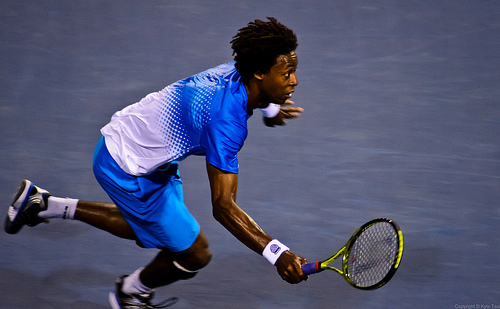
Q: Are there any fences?
A: No, there are no fences.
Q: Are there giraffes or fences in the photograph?
A: No, there are no fences or giraffes.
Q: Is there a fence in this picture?
A: No, there are no fences.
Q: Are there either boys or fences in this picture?
A: No, there are no fences or boys.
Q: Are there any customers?
A: No, there are no customers.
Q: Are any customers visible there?
A: No, there are no customers.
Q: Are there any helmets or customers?
A: No, there are no customers or helmets.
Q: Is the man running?
A: Yes, the man is running.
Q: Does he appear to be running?
A: Yes, the man is running.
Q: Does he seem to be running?
A: Yes, the man is running.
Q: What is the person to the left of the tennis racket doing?
A: The man is running.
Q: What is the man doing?
A: The man is running.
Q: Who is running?
A: The man is running.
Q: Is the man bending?
A: No, the man is running.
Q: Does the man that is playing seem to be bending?
A: No, the man is running.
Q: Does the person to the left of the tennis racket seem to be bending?
A: No, the man is running.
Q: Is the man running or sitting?
A: The man is running.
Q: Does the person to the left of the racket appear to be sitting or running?
A: The man is running.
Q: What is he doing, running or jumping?
A: The man is running.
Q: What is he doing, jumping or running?
A: The man is running.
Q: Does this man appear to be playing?
A: Yes, the man is playing.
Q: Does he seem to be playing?
A: Yes, the man is playing.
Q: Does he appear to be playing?
A: Yes, the man is playing.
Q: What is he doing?
A: The man is playing.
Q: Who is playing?
A: The man is playing.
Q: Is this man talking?
A: No, the man is playing.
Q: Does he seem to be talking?
A: No, the man is playing.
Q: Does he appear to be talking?
A: No, the man is playing.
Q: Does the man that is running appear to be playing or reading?
A: The man is playing.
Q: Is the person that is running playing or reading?
A: The man is playing.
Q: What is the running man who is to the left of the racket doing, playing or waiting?
A: The man is playing.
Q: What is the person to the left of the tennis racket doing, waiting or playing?
A: The man is playing.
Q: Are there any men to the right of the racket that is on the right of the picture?
A: No, the man is to the left of the racket.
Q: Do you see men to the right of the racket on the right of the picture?
A: No, the man is to the left of the racket.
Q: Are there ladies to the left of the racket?
A: No, there is a man to the left of the racket.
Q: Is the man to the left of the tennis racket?
A: Yes, the man is to the left of the tennis racket.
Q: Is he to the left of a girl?
A: No, the man is to the left of the tennis racket.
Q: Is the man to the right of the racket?
A: No, the man is to the left of the racket.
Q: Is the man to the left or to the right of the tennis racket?
A: The man is to the left of the tennis racket.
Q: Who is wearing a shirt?
A: The man is wearing a shirt.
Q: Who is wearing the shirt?
A: The man is wearing a shirt.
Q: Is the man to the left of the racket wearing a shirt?
A: Yes, the man is wearing a shirt.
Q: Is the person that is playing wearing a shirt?
A: Yes, the man is wearing a shirt.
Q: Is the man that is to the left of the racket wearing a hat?
A: No, the man is wearing a shirt.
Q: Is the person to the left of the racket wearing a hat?
A: No, the man is wearing a shirt.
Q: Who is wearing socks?
A: The man is wearing socks.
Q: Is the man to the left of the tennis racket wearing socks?
A: Yes, the man is wearing socks.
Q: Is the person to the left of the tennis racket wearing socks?
A: Yes, the man is wearing socks.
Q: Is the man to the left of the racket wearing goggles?
A: No, the man is wearing socks.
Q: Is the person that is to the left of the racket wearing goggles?
A: No, the man is wearing socks.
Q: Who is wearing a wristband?
A: The man is wearing a wristband.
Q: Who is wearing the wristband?
A: The man is wearing a wristband.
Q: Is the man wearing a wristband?
A: Yes, the man is wearing a wristband.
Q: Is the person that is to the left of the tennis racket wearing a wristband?
A: Yes, the man is wearing a wristband.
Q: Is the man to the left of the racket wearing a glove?
A: No, the man is wearing a wristband.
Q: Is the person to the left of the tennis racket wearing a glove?
A: No, the man is wearing a wristband.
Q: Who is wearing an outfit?
A: The man is wearing an outfit.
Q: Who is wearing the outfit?
A: The man is wearing an outfit.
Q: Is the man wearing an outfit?
A: Yes, the man is wearing an outfit.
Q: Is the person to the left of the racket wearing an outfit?
A: Yes, the man is wearing an outfit.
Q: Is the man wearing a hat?
A: No, the man is wearing an outfit.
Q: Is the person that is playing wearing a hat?
A: No, the man is wearing an outfit.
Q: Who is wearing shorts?
A: The man is wearing shorts.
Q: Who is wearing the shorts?
A: The man is wearing shorts.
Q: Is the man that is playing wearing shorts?
A: Yes, the man is wearing shorts.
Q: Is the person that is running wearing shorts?
A: Yes, the man is wearing shorts.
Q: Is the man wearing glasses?
A: No, the man is wearing shorts.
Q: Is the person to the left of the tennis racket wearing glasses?
A: No, the man is wearing shorts.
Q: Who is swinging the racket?
A: The man is swinging the racket.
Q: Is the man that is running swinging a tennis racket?
A: Yes, the man is swinging a tennis racket.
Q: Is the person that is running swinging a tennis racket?
A: Yes, the man is swinging a tennis racket.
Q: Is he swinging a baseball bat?
A: No, the man is swinging a tennis racket.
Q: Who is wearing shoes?
A: The man is wearing shoes.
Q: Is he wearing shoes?
A: Yes, the man is wearing shoes.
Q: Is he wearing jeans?
A: No, the man is wearing shoes.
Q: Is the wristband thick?
A: Yes, the wristband is thick.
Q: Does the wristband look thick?
A: Yes, the wristband is thick.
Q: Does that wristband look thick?
A: Yes, the wristband is thick.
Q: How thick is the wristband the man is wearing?
A: The wristband is thick.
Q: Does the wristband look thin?
A: No, the wristband is thick.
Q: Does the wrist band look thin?
A: No, the wrist band is thick.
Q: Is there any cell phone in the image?
A: No, there are no cell phones.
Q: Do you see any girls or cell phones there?
A: No, there are no cell phones or girls.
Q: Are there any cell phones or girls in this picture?
A: No, there are no cell phones or girls.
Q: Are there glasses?
A: No, there are no glasses.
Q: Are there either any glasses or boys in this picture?
A: No, there are no glasses or boys.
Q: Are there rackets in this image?
A: Yes, there is a racket.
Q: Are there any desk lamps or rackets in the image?
A: Yes, there is a racket.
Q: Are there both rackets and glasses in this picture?
A: No, there is a racket but no glasses.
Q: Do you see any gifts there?
A: No, there are no gifts.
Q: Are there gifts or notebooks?
A: No, there are no gifts or notebooks.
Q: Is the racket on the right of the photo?
A: Yes, the racket is on the right of the image.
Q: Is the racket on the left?
A: No, the racket is on the right of the image.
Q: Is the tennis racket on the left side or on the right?
A: The tennis racket is on the right of the image.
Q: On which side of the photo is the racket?
A: The racket is on the right of the image.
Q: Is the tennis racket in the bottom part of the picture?
A: Yes, the tennis racket is in the bottom of the image.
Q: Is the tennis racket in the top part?
A: No, the tennis racket is in the bottom of the image.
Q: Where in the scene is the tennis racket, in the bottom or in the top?
A: The tennis racket is in the bottom of the image.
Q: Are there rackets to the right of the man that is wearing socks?
A: Yes, there is a racket to the right of the man.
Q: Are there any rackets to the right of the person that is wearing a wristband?
A: Yes, there is a racket to the right of the man.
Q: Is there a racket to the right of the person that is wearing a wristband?
A: Yes, there is a racket to the right of the man.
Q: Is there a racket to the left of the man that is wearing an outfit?
A: No, the racket is to the right of the man.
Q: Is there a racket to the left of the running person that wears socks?
A: No, the racket is to the right of the man.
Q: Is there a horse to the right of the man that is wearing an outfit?
A: No, there is a racket to the right of the man.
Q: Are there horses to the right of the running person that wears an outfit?
A: No, there is a racket to the right of the man.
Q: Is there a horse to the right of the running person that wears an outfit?
A: No, there is a racket to the right of the man.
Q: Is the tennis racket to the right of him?
A: Yes, the tennis racket is to the right of the man.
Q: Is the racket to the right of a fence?
A: No, the racket is to the right of the man.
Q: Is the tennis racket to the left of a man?
A: No, the tennis racket is to the right of a man.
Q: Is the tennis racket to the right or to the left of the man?
A: The tennis racket is to the right of the man.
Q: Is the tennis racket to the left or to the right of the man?
A: The tennis racket is to the right of the man.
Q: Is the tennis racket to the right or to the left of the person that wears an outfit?
A: The tennis racket is to the right of the man.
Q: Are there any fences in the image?
A: No, there are no fences.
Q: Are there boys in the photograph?
A: No, there are no boys.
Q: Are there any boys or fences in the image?
A: No, there are no boys or fences.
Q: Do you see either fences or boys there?
A: No, there are no boys or fences.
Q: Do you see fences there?
A: No, there are no fences.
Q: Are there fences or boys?
A: No, there are no fences or boys.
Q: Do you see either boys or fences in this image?
A: No, there are no fences or boys.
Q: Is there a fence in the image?
A: No, there are no fences.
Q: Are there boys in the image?
A: No, there are no boys.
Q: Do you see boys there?
A: No, there are no boys.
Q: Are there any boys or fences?
A: No, there are no boys or fences.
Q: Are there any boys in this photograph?
A: No, there are no boys.